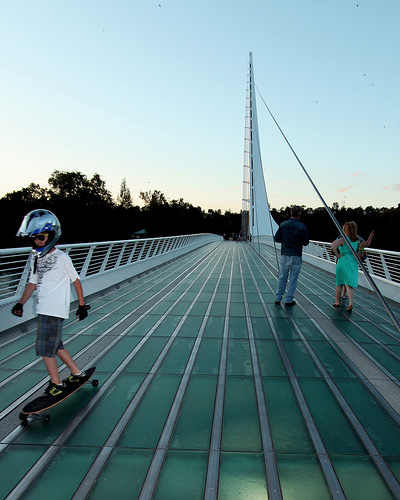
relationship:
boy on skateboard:
[11, 201, 93, 398] [20, 362, 102, 428]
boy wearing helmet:
[11, 201, 93, 398] [16, 205, 65, 261]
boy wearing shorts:
[11, 201, 93, 398] [33, 313, 67, 364]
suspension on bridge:
[251, 81, 400, 339] [3, 226, 400, 491]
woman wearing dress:
[328, 219, 367, 317] [336, 233, 363, 288]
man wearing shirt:
[273, 206, 317, 311] [276, 218, 315, 257]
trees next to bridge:
[2, 159, 398, 247] [3, 226, 400, 491]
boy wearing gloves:
[11, 201, 93, 398] [9, 299, 95, 324]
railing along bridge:
[3, 230, 227, 331] [3, 226, 400, 491]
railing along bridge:
[249, 227, 400, 311] [3, 226, 400, 491]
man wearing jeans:
[273, 206, 317, 311] [274, 253, 305, 306]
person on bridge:
[273, 206, 317, 311] [3, 226, 400, 491]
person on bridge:
[328, 219, 367, 317] [3, 226, 400, 491]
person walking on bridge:
[273, 206, 317, 311] [3, 226, 400, 491]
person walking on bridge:
[328, 219, 367, 317] [3, 226, 400, 491]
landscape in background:
[3, 160, 400, 248] [3, 0, 398, 254]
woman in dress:
[328, 219, 367, 317] [336, 233, 363, 288]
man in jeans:
[273, 206, 317, 311] [274, 253, 305, 306]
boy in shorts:
[11, 201, 93, 398] [33, 313, 67, 364]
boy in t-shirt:
[11, 201, 93, 398] [25, 247, 80, 321]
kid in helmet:
[11, 201, 93, 398] [16, 205, 65, 261]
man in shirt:
[273, 206, 317, 311] [276, 218, 315, 257]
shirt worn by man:
[276, 218, 315, 257] [273, 206, 317, 311]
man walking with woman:
[273, 206, 317, 311] [328, 219, 367, 317]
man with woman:
[273, 206, 317, 311] [328, 219, 367, 317]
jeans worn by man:
[274, 253, 305, 306] [273, 206, 317, 311]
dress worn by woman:
[336, 233, 363, 288] [328, 219, 367, 317]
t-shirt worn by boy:
[25, 247, 80, 321] [11, 201, 93, 398]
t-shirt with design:
[25, 247, 80, 321] [32, 253, 62, 305]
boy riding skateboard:
[11, 201, 93, 398] [20, 362, 102, 428]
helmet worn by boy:
[16, 205, 65, 261] [11, 201, 93, 398]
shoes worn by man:
[270, 297, 298, 311] [273, 206, 317, 311]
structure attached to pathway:
[236, 52, 272, 250] [2, 229, 400, 491]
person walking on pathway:
[273, 206, 317, 311] [2, 229, 400, 491]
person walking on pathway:
[328, 219, 367, 317] [2, 229, 400, 491]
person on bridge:
[11, 201, 93, 398] [3, 226, 400, 491]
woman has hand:
[328, 219, 367, 317] [336, 251, 346, 260]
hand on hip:
[336, 251, 346, 260] [337, 254, 349, 271]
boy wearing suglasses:
[11, 201, 93, 398] [30, 235, 49, 244]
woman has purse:
[328, 219, 367, 317] [357, 241, 371, 262]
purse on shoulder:
[357, 241, 371, 262] [355, 238, 363, 246]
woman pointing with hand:
[328, 219, 367, 317] [368, 226, 377, 234]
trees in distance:
[2, 159, 398, 247] [3, 7, 400, 249]